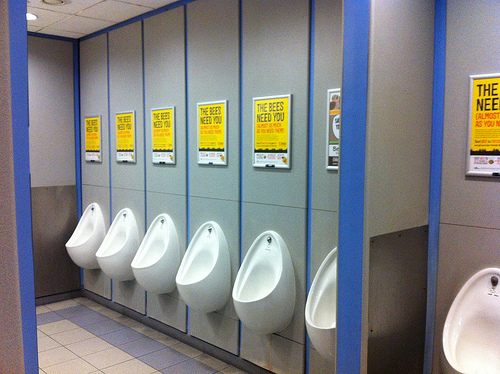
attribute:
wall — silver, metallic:
[368, 225, 430, 374]